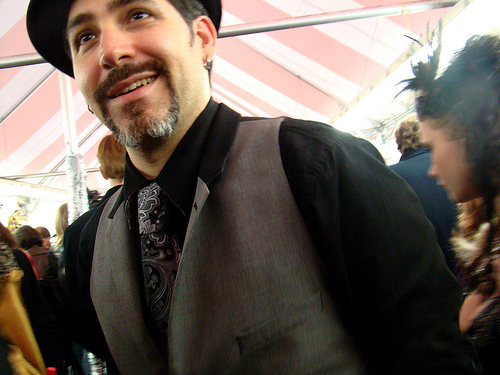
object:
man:
[26, 0, 461, 369]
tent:
[4, 0, 437, 196]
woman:
[403, 55, 499, 349]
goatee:
[94, 64, 181, 146]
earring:
[203, 57, 218, 73]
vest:
[78, 116, 356, 373]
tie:
[126, 182, 186, 334]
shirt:
[73, 125, 463, 373]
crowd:
[0, 185, 104, 364]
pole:
[3, 0, 444, 72]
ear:
[193, 14, 217, 72]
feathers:
[394, 24, 448, 97]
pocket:
[232, 292, 345, 351]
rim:
[24, 4, 39, 39]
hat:
[28, 0, 234, 72]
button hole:
[192, 198, 205, 213]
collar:
[112, 99, 225, 215]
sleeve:
[292, 137, 479, 369]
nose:
[96, 26, 142, 68]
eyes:
[69, 5, 159, 47]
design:
[137, 240, 169, 286]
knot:
[139, 188, 171, 231]